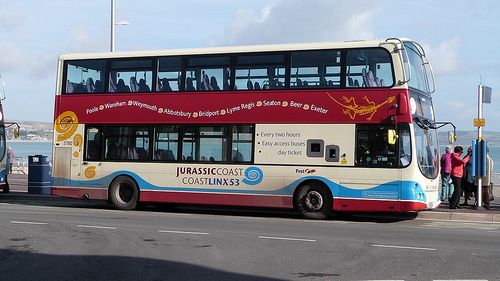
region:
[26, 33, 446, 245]
a double decker bus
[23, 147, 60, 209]
the trash bin is blue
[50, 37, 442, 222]
red and white two story bus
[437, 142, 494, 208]
people waiting at the bus stop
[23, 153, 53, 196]
blue trash can next to the road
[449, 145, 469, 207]
woman in a red coat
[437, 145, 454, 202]
woman in a purple coat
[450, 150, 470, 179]
red coat on the woman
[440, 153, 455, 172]
purple jacket on the woman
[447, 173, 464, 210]
black pants on the woman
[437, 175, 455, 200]
blue pants on the woman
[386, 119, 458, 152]
rear view mirrors on the bus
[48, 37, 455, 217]
the double decker bus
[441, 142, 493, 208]
the people near the bus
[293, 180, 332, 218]
the wheel on the bus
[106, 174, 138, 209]
the wheel on the bus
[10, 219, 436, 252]
the white lines on the ground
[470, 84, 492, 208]
the pole near the people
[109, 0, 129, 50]
the light pole behind the bus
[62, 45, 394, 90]
the passenger windows on the second floor of the bus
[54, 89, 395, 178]
the yellow paint on the bus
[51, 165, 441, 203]
the blue paint on the bus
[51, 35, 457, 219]
Large colorful bus parked on waterfront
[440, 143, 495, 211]
Group of people standing near front of bus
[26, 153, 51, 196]
Gray and white trash can behind bus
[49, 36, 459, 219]
Red, white, and blue double-decker bus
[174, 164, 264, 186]
Advertisement on bus for "JurassicCoast"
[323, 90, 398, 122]
Yellow image of dinosaur skeleton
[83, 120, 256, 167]
Windows on lower deck of bus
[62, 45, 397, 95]
Windows in top deck of bus showing empty passenger seats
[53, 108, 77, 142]
Bright yellow spiral painted on bus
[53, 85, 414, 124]
Red stripe with white text and yellow designs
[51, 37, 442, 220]
Red, white and blue double-decker passenger bus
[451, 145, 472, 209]
Person wearing a red jacket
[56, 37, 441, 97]
Upper deck of double-decker bus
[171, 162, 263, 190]
Advertisement on the side of the bus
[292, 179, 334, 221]
Right front wheel of double-decker bus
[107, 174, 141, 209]
Rear right wheel of double-decker bus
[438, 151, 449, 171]
Woman wearing a fuchsia colored jacket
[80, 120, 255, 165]
Passenger windows on the right side of the bus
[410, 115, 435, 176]
Windshield of the lower deck of the bus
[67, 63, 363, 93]
Passengers sitting on the upper deck of the bus